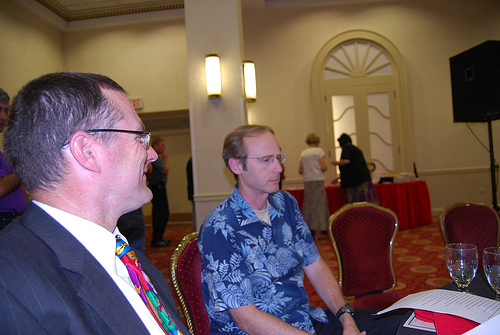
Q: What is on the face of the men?
A: Glasses.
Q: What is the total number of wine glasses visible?
A: 2.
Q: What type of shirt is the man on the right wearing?
A: Floral.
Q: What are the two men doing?
A: Sitting.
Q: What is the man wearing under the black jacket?
A: White shirt.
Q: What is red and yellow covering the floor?
A: The carpet.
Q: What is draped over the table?
A: Tablecloth.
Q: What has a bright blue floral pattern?
A: Gentleman's shirt.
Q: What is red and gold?
A: The chairs.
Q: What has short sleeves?
A: Gentleman's shirt.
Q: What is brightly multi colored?
A: Gentleman's tie.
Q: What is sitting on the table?
A: Water glasses.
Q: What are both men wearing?
A: Glasses.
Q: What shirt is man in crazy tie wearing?
A: White collared.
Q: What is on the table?
A: Glass.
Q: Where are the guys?
A: Sitting.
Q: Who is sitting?
A: The guys.